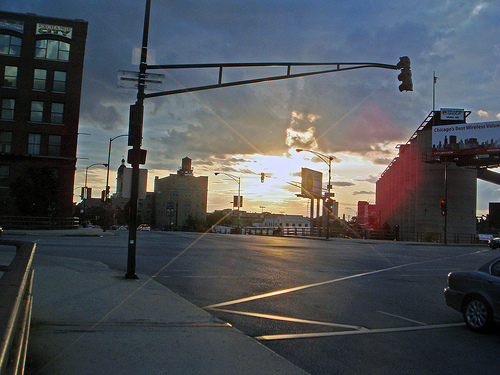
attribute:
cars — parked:
[95, 202, 134, 250]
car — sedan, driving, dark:
[406, 238, 498, 311]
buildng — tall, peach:
[22, 19, 73, 211]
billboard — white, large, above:
[285, 149, 332, 201]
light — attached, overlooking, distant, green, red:
[334, 26, 447, 95]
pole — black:
[113, 32, 193, 286]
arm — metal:
[173, 36, 328, 111]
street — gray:
[194, 224, 413, 359]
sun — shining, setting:
[238, 119, 373, 255]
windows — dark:
[19, 52, 66, 161]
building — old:
[164, 162, 282, 245]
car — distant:
[135, 204, 200, 252]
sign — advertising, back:
[204, 166, 291, 240]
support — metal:
[117, 118, 168, 309]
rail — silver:
[385, 125, 452, 165]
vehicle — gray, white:
[436, 263, 499, 340]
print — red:
[421, 120, 497, 148]